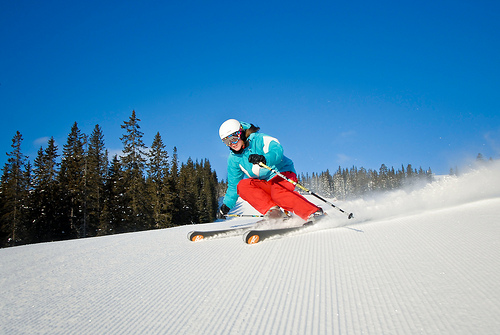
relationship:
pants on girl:
[235, 171, 321, 222] [215, 117, 324, 226]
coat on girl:
[217, 132, 301, 211] [215, 117, 324, 226]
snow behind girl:
[317, 157, 500, 233] [215, 117, 324, 226]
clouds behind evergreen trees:
[27, 121, 166, 182] [0, 130, 32, 251]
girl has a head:
[215, 117, 324, 226] [217, 117, 249, 155]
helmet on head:
[217, 117, 242, 140] [217, 117, 249, 155]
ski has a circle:
[186, 211, 273, 244] [190, 232, 206, 243]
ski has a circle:
[243, 218, 319, 246] [245, 230, 262, 247]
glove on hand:
[247, 151, 268, 167] [246, 150, 269, 168]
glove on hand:
[212, 202, 232, 222] [214, 200, 233, 220]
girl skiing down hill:
[211, 117, 329, 229] [1, 158, 499, 335]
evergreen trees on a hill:
[0, 130, 32, 251] [1, 158, 499, 335]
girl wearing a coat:
[211, 117, 329, 229] [217, 132, 297, 211]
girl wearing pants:
[211, 117, 329, 229] [235, 171, 321, 222]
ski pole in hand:
[256, 160, 357, 222] [246, 150, 269, 168]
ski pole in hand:
[219, 211, 266, 221] [214, 200, 233, 220]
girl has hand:
[211, 117, 329, 229] [246, 150, 269, 168]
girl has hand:
[211, 117, 329, 229] [214, 200, 233, 220]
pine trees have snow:
[320, 169, 332, 197] [308, 172, 399, 195]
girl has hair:
[211, 117, 329, 229] [238, 119, 260, 138]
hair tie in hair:
[238, 118, 251, 133] [238, 119, 260, 138]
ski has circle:
[186, 211, 273, 244] [190, 235, 204, 242]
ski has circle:
[243, 218, 319, 246] [248, 234, 259, 244]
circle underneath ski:
[190, 235, 204, 242] [186, 211, 273, 244]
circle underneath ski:
[248, 234, 259, 244] [243, 218, 319, 246]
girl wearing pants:
[215, 117, 324, 226] [235, 171, 321, 222]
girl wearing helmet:
[215, 117, 324, 226] [217, 117, 242, 140]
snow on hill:
[0, 159, 499, 334] [1, 152, 499, 334]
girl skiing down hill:
[215, 117, 324, 226] [1, 152, 499, 334]